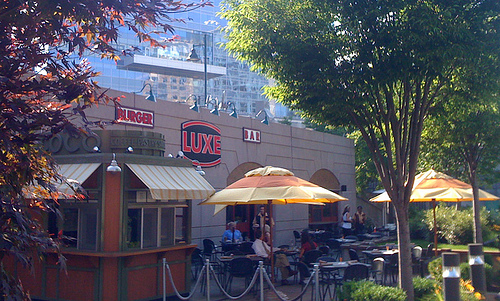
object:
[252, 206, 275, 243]
people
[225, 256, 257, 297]
chair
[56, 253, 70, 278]
leaf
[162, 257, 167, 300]
bar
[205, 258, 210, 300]
bar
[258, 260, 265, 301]
bar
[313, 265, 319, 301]
bar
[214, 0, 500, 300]
tree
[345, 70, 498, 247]
tree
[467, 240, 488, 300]
barrier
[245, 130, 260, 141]
text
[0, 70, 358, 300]
building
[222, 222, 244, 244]
people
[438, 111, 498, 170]
branch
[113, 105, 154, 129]
sign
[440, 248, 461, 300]
barrier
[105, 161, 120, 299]
shop part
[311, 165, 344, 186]
edge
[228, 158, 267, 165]
edge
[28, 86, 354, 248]
wall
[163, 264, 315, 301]
chain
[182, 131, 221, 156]
red lettering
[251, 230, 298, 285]
people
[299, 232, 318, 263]
people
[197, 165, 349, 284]
umbrella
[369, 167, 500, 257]
umbrella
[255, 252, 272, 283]
chair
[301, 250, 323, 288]
chair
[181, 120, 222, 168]
sign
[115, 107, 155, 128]
lettering